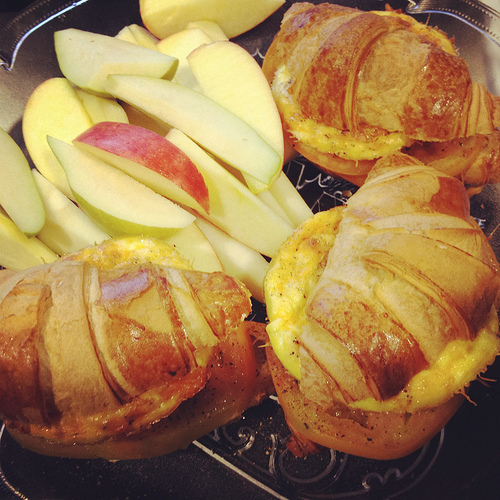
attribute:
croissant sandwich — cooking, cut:
[269, 3, 497, 191]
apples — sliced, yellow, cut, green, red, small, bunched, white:
[10, 36, 294, 282]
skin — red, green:
[80, 59, 194, 215]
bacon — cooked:
[10, 269, 181, 426]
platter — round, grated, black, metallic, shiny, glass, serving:
[6, 9, 498, 486]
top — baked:
[279, 8, 476, 136]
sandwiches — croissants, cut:
[10, 12, 495, 469]